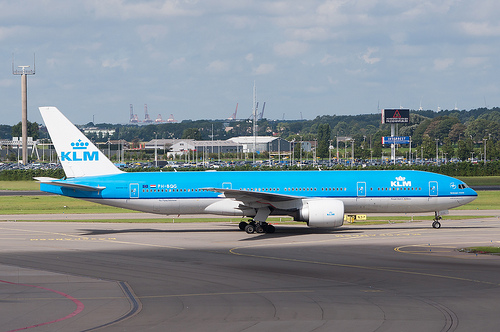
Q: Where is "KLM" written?
A: On plane's tail.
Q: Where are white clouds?
A: In the sky.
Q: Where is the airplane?
A: On the runway.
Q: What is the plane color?
A: Blue.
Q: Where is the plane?
A: Airport.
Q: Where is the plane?
A: Runway.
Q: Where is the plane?
A: Runway.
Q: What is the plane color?
A: Blue.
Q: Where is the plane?
A: Runway.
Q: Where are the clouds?
A: Sky.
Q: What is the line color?
A: Yellow.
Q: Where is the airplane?
A: Runway.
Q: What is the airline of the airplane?
A: KLM.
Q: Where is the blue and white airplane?
A: Runway.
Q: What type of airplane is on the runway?
A: Passenger.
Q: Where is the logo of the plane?
A: Tail.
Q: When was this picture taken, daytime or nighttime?
A: Daytime.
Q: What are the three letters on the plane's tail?
A: KLM.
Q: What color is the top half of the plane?
A: Blue.